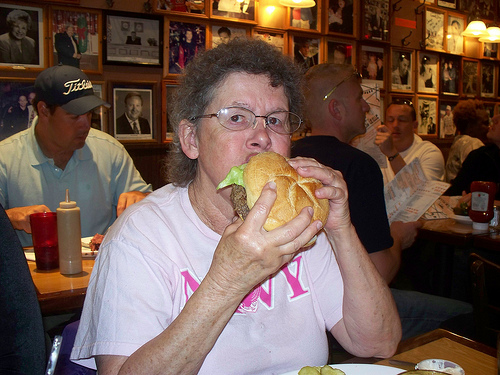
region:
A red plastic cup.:
[28, 212, 60, 271]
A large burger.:
[227, 159, 331, 240]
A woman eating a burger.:
[67, 42, 431, 372]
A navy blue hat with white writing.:
[34, 64, 106, 114]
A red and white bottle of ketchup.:
[471, 179, 494, 229]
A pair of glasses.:
[184, 106, 304, 136]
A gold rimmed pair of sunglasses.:
[324, 67, 364, 100]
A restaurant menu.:
[381, 158, 451, 223]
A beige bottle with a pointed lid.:
[59, 187, 83, 276]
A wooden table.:
[323, 328, 495, 373]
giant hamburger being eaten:
[216, 150, 342, 245]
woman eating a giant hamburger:
[164, 46, 354, 250]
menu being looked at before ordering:
[378, 158, 448, 238]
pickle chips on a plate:
[297, 361, 342, 373]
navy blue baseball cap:
[25, 59, 110, 127]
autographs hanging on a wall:
[365, 36, 462, 102]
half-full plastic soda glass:
[26, 210, 63, 273]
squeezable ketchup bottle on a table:
[465, 177, 492, 238]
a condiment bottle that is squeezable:
[48, 193, 85, 280]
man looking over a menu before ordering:
[358, 100, 445, 185]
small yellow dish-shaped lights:
[458, 12, 498, 53]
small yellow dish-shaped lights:
[244, 0, 322, 14]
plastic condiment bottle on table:
[52, 185, 86, 280]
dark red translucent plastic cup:
[26, 207, 66, 273]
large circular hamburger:
[215, 146, 335, 256]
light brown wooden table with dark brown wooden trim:
[232, 322, 495, 372]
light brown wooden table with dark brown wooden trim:
[0, 211, 202, 318]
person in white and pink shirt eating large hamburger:
[69, 32, 421, 373]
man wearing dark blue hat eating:
[0, 61, 167, 268]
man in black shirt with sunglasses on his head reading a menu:
[269, 56, 476, 370]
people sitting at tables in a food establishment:
[4, 5, 494, 369]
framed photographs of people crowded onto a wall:
[1, 2, 496, 144]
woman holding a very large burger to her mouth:
[76, 36, 403, 368]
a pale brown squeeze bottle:
[56, 186, 86, 276]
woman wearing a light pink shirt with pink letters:
[72, 178, 343, 370]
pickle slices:
[297, 362, 350, 374]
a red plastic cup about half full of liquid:
[29, 209, 61, 274]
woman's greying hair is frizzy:
[163, 37, 304, 187]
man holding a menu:
[307, 57, 450, 279]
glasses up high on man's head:
[381, 94, 422, 153]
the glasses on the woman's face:
[176, 105, 302, 135]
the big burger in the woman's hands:
[218, 150, 331, 247]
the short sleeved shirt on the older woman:
[72, 175, 349, 374]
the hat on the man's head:
[29, 64, 106, 117]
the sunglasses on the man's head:
[323, 65, 362, 103]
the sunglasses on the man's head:
[385, 98, 417, 110]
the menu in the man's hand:
[382, 152, 449, 228]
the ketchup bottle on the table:
[470, 179, 495, 228]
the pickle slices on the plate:
[297, 365, 344, 374]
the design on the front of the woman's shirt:
[176, 253, 309, 316]